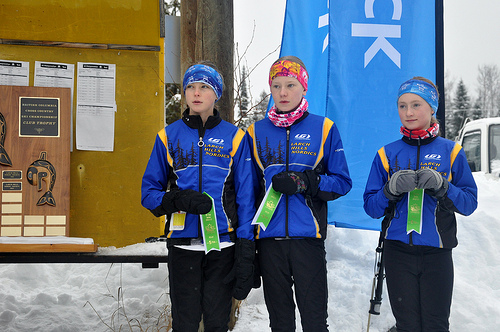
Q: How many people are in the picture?
A: Three.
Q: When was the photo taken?
A: Daytime.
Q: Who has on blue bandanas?
A: Two people.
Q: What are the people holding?
A: Green ribbons.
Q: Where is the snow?
A: On the ground.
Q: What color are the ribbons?
A: Green.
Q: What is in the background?
A: Trees.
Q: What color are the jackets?
A: Blue.